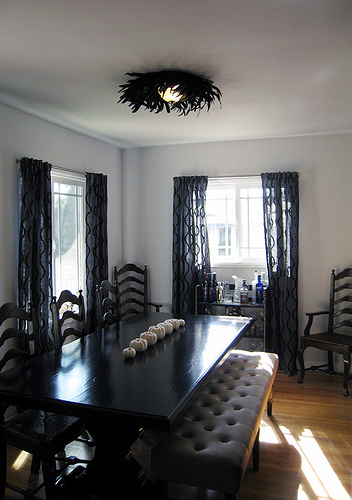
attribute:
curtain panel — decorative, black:
[170, 174, 214, 315]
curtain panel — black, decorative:
[259, 170, 298, 378]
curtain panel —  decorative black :
[23, 158, 301, 335]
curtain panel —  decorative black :
[19, 150, 305, 377]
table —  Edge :
[142, 397, 184, 434]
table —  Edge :
[128, 396, 191, 436]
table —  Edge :
[141, 382, 190, 430]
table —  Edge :
[131, 380, 198, 426]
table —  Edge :
[130, 389, 189, 442]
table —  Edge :
[117, 376, 209, 436]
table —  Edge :
[121, 396, 191, 451]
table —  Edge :
[139, 389, 184, 427]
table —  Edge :
[143, 378, 199, 440]